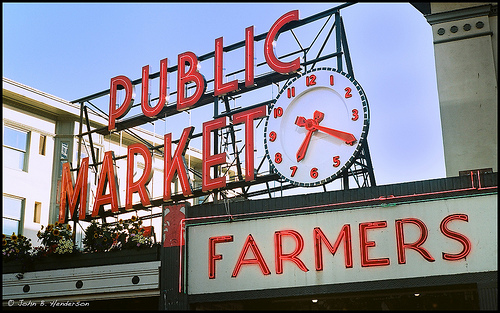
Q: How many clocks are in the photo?
A: One.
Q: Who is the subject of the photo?
A: The sign.